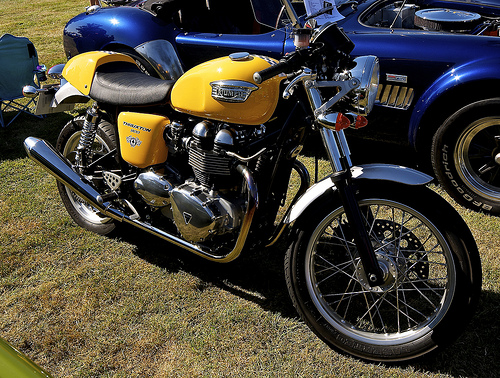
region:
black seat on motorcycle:
[95, 49, 161, 105]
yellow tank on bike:
[172, 47, 282, 112]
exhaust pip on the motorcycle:
[25, 137, 255, 292]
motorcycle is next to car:
[38, 1, 496, 338]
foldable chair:
[0, 32, 45, 132]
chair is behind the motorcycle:
[3, 24, 63, 170]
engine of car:
[362, 4, 496, 39]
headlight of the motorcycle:
[359, 50, 386, 121]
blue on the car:
[64, 4, 201, 77]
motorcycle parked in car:
[37, 160, 496, 375]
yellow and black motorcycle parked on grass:
[25, 30, 480, 360]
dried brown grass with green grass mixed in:
[1, 1, 492, 371]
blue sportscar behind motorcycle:
[31, 1, 493, 351]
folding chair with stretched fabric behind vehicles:
[0, 22, 35, 132]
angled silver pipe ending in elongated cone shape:
[20, 125, 251, 260]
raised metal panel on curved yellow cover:
[170, 50, 285, 125]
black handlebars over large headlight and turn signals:
[250, 30, 380, 130]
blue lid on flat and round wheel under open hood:
[340, 1, 495, 36]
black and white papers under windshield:
[292, 0, 343, 27]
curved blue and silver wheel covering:
[57, 7, 182, 72]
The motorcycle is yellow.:
[21, 0, 481, 362]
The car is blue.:
[63, 1, 499, 153]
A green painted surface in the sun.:
[0, 335, 55, 377]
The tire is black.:
[286, 175, 481, 371]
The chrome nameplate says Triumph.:
[209, 79, 257, 104]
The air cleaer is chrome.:
[411, 5, 488, 32]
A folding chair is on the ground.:
[1, 30, 41, 132]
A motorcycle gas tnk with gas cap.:
[171, 52, 288, 125]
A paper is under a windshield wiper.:
[303, 0, 346, 27]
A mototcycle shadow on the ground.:
[116, 228, 497, 376]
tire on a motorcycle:
[275, 176, 491, 362]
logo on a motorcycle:
[199, 73, 263, 110]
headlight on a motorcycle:
[340, 50, 385, 123]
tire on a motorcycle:
[42, 105, 132, 240]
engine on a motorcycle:
[153, 110, 255, 197]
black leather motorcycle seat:
[79, 53, 186, 115]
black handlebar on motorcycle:
[246, 49, 310, 104]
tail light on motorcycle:
[19, 80, 40, 100]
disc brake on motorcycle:
[356, 220, 428, 290]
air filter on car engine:
[415, 4, 482, 38]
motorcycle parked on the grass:
[22, 29, 487, 367]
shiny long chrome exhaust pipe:
[25, 133, 258, 267]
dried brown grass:
[23, 263, 215, 365]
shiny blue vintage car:
[63, 0, 496, 214]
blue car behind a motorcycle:
[65, 0, 499, 191]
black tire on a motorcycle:
[289, 182, 481, 373]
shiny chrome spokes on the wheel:
[321, 213, 440, 332]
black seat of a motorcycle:
[99, 53, 179, 108]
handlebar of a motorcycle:
[249, 57, 315, 96]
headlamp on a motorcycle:
[342, 49, 387, 122]